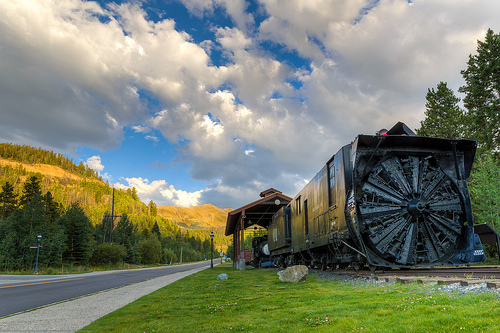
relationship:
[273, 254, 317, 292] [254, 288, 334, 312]
rock on top of grass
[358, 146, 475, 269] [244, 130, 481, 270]
fan attached to train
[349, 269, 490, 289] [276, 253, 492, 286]
ties attached to tracks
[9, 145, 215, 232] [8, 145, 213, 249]
sunlight shining on hills